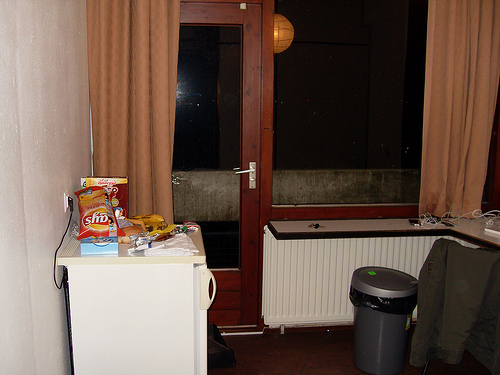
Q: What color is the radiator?
A: White.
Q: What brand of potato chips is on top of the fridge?
A: Lay's.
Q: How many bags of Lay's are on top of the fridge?
A: One.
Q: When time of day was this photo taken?
A: Nighttime.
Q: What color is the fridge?
A: White.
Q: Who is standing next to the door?
A: No one.